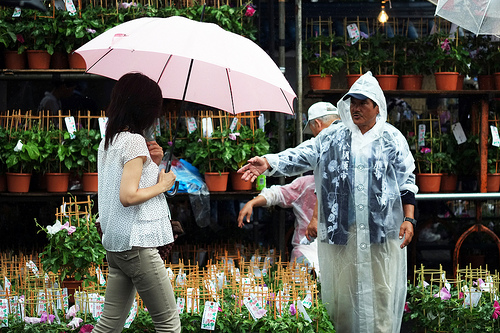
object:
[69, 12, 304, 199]
umbrella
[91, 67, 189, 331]
woman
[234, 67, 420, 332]
man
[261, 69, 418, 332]
parka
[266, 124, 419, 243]
hawaiian shirt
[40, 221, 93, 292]
plants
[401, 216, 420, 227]
watch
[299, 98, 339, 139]
man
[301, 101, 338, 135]
hat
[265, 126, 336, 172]
arm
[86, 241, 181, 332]
pants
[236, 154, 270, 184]
hand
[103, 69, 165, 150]
hair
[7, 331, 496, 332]
ground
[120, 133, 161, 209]
arm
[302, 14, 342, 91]
plants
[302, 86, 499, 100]
shelf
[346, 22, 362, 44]
tag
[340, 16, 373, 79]
plant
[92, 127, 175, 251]
blouse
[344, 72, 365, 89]
pot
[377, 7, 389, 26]
light buld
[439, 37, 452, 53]
flower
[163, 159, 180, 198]
handle